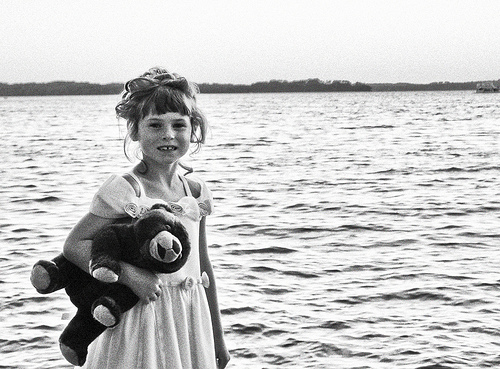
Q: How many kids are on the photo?
A: One.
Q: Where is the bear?
A: In the hands of the girl.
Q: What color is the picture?
A: Black and white.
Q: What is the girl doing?
A: Looking at the camera.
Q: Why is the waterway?
A: It is windy.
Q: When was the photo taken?
A: Daytime.